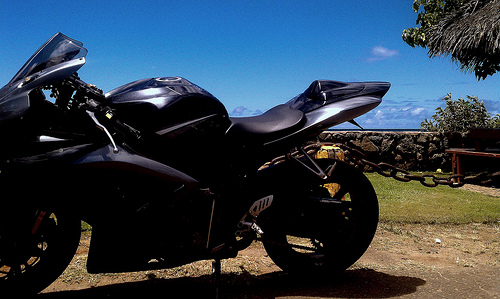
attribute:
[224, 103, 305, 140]
seat — black 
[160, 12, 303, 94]
sky — blue 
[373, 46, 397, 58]
cloud — white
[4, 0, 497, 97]
sky — blue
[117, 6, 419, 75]
sky — bright, blue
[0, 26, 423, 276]
motorcycle — beautiful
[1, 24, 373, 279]
motorcycle — black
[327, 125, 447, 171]
wall — stone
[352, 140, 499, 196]
chain — metallic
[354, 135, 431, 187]
chain — big 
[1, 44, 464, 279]
motorcycle — black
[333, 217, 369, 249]
wheel — part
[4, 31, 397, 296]
motorcycle — dark, shiny, nice, parked, polished, clean, black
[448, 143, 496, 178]
table — brown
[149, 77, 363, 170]
seat — black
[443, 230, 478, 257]
ground — part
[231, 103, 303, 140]
seat — black